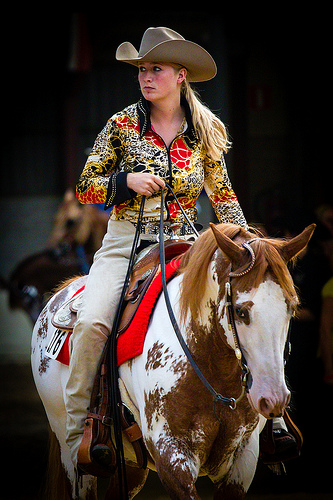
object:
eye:
[232, 296, 251, 327]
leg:
[62, 259, 130, 463]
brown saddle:
[50, 236, 196, 341]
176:
[46, 329, 65, 360]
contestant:
[65, 26, 248, 479]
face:
[220, 268, 300, 412]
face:
[127, 60, 176, 98]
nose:
[249, 389, 297, 418]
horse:
[6, 243, 102, 310]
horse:
[46, 189, 110, 251]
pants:
[59, 214, 135, 476]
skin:
[185, 270, 266, 442]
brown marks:
[146, 343, 166, 370]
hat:
[115, 25, 217, 82]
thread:
[108, 183, 250, 408]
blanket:
[53, 253, 186, 367]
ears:
[208, 221, 245, 263]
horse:
[30, 213, 318, 500]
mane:
[183, 233, 218, 311]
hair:
[179, 64, 233, 161]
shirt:
[73, 96, 247, 247]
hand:
[125, 170, 166, 199]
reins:
[103, 174, 250, 444]